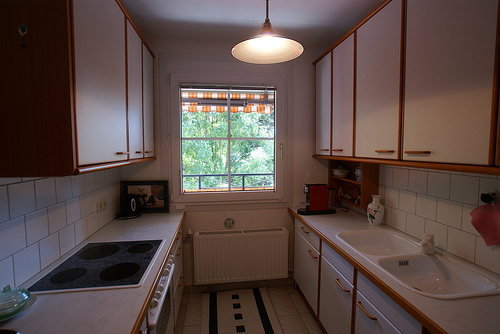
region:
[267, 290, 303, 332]
Tiles on the floor.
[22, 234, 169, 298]
A stove top.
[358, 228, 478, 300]
A white kitchen sink.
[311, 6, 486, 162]
Four cabinets above the sink.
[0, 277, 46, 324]
A glass dish on the counter top.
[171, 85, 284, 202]
A kitchen window.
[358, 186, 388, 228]
A vase next to the sink.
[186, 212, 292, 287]
An airconditioning/heating unit.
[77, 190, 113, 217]
A power outlet.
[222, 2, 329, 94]
A light hanging from the ceiling.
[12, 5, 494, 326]
a kitchen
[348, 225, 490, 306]
two white sinks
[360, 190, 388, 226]
a white vase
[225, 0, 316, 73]
light fixture on the ceiling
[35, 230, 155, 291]
burners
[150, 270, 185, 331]
a stove with a white handle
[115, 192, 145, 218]
a black kettle on a counter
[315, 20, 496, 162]
white cabinets with wood frames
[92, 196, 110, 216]
an electric outlet on a wall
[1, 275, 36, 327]
a green dish on a counter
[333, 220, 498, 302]
A white kitchen sink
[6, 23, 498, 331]
A kitchen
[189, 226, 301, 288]
A furnace below a window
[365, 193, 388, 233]
A vase with a design on it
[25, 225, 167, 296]
A glass stovetop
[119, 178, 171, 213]
A picture on the end of the cabinet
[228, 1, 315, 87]
The hanging kitchen light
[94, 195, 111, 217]
A electrical outlet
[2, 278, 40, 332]
A glass dish on the counter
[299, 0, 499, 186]
Overhead cabinets in the kitchen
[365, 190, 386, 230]
white vase with a pink flower on it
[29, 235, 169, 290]
stove top with four elements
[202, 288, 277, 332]
floor runner with white stripes and dashes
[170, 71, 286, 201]
large window with view of trees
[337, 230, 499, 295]
white kitchen sink with a white faucet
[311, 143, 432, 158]
four wooden kitchen cabinet handles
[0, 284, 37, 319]
green glass candy dish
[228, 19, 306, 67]
bright light hanging from the ceiling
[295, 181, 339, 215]
red and black appliance sitting on kitchen cabinet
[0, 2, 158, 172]
wooden kitchen cabinets with white doors and wooden handles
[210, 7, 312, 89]
Light hanging from ceiling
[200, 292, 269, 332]
Small black dotted rug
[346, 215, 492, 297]
White colored double sink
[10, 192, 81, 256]
White tile back splash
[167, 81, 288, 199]
Large window in back of kitchen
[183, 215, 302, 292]
Air conditioning unit toward floor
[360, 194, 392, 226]
Small vase on top of counter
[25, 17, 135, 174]
Wooden cabinet with white door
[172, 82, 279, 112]
White and orange over hang on window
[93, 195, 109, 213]
Electrical outlet on wall